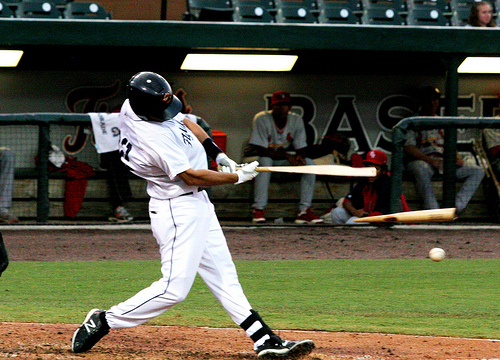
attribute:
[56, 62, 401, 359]
player — standing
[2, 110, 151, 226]
fence — black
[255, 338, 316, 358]
shoe — black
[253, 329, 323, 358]
shoe — black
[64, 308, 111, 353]
shoe — black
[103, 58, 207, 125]
helmet — black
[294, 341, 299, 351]
shoe — black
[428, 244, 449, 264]
baseball — white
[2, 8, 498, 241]
dugout — behind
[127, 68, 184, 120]
baseball helmet — black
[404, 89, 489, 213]
player — white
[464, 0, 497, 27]
spectator — standing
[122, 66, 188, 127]
helmet — black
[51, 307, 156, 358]
shoes — white, black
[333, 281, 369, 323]
lawn — green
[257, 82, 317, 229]
player — standing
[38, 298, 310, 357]
shoes — black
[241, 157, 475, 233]
bat — brown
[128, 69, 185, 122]
hat — black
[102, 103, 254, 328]
uniform — white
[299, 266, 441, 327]
field — brown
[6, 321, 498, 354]
box — behind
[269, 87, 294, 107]
cap — red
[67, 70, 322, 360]
person — wearing white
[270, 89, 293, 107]
hat — red